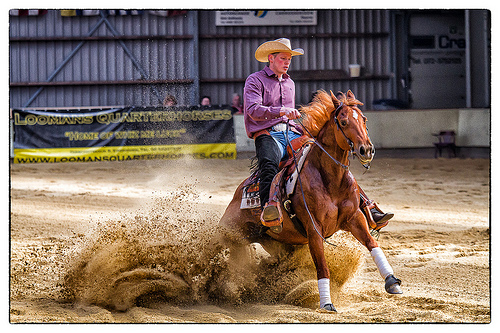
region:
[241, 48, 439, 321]
the horse is brown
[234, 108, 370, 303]
the horse is brown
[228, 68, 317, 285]
the horse is brown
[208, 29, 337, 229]
the horse is brown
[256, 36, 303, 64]
light brown cowboy hat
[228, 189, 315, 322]
the horse is brown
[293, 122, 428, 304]
the horse is brown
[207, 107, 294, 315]
the horse is brown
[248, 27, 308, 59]
cap of the person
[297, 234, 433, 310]
legs of the horse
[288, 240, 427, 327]
legs of running horse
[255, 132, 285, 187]
leg of the person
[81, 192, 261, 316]
a beautiful view of sand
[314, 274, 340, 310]
a small white paint on leg of horse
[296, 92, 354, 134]
hairs of the horse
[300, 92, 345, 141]
raising hairs of horse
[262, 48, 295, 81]
face of the man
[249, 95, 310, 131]
hand of the man